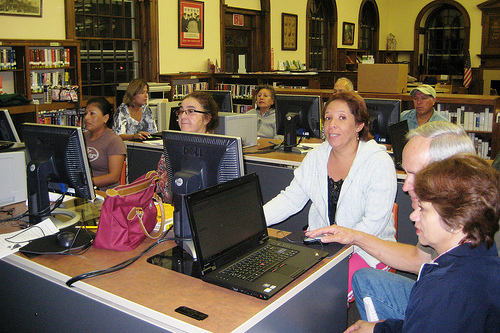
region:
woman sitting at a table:
[261, 90, 401, 300]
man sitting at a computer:
[392, 81, 444, 131]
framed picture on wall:
[175, 0, 200, 46]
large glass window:
[70, 0, 150, 102]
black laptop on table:
[181, 171, 321, 296]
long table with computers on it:
[0, 185, 350, 330]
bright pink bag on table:
[91, 165, 162, 245]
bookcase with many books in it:
[10, 32, 80, 122]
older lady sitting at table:
[350, 151, 497, 326]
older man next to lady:
[305, 120, 481, 272]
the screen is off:
[168, 161, 322, 326]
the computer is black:
[172, 162, 329, 307]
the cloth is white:
[255, 123, 410, 258]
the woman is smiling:
[310, 82, 373, 158]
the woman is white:
[282, 72, 399, 270]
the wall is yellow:
[162, 5, 182, 85]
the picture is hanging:
[168, 0, 215, 60]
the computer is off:
[175, 167, 332, 307]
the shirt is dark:
[412, 233, 494, 330]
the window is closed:
[64, 5, 171, 100]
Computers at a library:
[7, 48, 459, 331]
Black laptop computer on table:
[164, 187, 329, 288]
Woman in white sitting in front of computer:
[257, 78, 404, 263]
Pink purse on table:
[74, 160, 171, 256]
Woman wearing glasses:
[165, 95, 218, 141]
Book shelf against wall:
[14, 26, 85, 123]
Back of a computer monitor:
[11, 110, 100, 265]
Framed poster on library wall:
[171, 5, 213, 51]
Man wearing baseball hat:
[402, 77, 446, 127]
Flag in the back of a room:
[454, 43, 486, 93]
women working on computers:
[13, 70, 296, 260]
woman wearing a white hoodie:
[265, 86, 399, 226]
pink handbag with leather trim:
[88, 166, 168, 251]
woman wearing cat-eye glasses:
[161, 83, 229, 141]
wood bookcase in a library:
[2, 27, 92, 119]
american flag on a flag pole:
[458, 42, 473, 97]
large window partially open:
[71, 1, 158, 96]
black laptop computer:
[181, 170, 326, 307]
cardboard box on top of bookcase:
[354, 55, 415, 97]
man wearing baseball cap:
[391, 80, 447, 121]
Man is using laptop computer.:
[290, 121, 486, 326]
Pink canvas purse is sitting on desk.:
[90, 167, 183, 259]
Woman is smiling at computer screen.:
[168, 90, 223, 154]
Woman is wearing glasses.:
[168, 103, 214, 120]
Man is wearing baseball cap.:
[405, 77, 443, 109]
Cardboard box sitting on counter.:
[352, 59, 413, 98]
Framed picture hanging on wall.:
[173, 1, 211, 53]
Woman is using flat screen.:
[19, 116, 103, 263]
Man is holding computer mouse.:
[293, 217, 349, 250]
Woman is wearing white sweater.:
[256, 137, 399, 270]